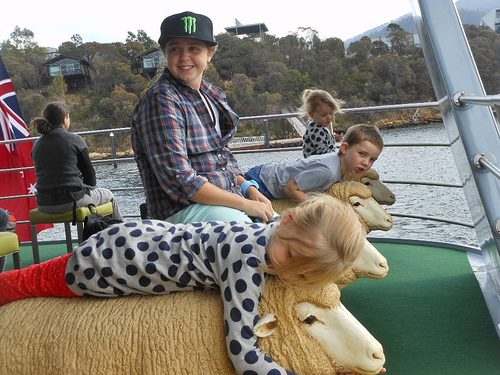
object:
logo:
[181, 16, 198, 33]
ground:
[0, 241, 500, 374]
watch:
[240, 179, 262, 200]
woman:
[129, 12, 281, 225]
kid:
[301, 87, 339, 158]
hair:
[256, 192, 370, 290]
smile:
[177, 64, 195, 73]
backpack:
[83, 203, 124, 244]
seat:
[0, 230, 23, 270]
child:
[0, 195, 387, 374]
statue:
[264, 180, 395, 235]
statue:
[332, 237, 388, 290]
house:
[42, 53, 92, 93]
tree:
[311, 35, 343, 62]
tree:
[369, 39, 388, 56]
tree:
[363, 54, 419, 106]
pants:
[0, 250, 83, 305]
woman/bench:
[32, 101, 124, 221]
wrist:
[241, 181, 257, 193]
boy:
[241, 123, 384, 204]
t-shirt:
[259, 152, 342, 200]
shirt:
[130, 67, 244, 221]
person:
[130, 10, 276, 225]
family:
[1, 10, 385, 374]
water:
[33, 119, 500, 247]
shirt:
[65, 218, 291, 374]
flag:
[0, 56, 58, 243]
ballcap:
[157, 11, 217, 47]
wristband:
[240, 179, 259, 195]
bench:
[30, 201, 117, 265]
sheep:
[0, 281, 386, 373]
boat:
[0, 0, 500, 374]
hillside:
[0, 24, 500, 159]